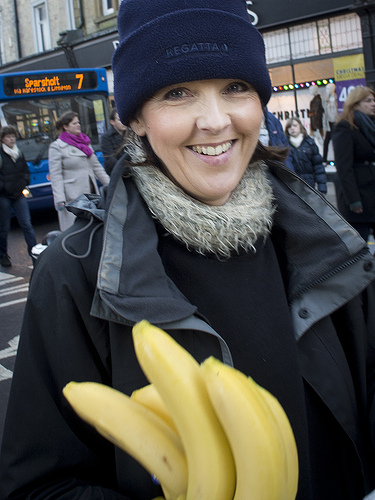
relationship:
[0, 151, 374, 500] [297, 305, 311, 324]
jacket as a button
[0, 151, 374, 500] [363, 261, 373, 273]
jacket has a button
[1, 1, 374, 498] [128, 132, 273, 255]
woman wearing a scarf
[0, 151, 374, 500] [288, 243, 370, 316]
jacket has a zipper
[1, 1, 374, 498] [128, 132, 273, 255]
woman has a scarf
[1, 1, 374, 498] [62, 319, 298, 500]
woman holding bananas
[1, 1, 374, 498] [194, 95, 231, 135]
woman has a nose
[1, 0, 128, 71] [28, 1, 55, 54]
building has a window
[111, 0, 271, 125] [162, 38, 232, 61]
hat has writing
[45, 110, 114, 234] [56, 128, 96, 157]
woman wearing a scarf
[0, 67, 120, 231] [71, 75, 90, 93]
bus has numbers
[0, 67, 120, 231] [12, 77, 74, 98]
bus has writing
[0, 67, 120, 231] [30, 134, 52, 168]
bus has windshield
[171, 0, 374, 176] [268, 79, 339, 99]
building has lights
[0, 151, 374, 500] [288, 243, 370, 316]
coat has a zipper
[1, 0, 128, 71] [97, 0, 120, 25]
building has a window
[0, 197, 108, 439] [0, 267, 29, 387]
street has paint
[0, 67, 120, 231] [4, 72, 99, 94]
bus has lighted route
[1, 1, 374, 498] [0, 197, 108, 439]
woman standing on street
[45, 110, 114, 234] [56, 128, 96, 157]
woman has a scarf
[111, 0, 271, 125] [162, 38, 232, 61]
cap has logo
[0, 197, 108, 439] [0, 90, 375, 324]
street full of people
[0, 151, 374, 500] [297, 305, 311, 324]
jacket has a button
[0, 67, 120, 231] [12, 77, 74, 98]
bus has orange words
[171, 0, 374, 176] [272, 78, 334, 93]
building has lights